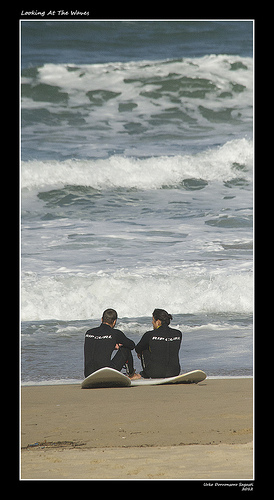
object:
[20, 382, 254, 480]
sand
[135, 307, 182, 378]
people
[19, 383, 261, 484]
beach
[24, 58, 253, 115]
seafoam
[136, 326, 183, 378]
wetsuit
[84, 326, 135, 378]
wetsuit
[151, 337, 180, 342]
white text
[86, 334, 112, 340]
white text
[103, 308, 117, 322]
hair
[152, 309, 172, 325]
hair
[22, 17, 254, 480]
picture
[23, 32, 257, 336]
water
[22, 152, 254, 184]
wave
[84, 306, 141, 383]
person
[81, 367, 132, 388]
surfboard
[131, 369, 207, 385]
surfboard